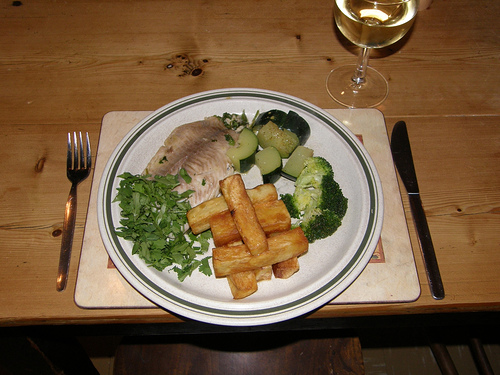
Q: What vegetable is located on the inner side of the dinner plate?
A: Golden brown french fried.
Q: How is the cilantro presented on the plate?
A: Finely chopped.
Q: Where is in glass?
A: Wine.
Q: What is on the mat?
A: Plate of food.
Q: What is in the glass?
A: Wine.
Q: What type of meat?
A: Fish.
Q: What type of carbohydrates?
A: Potatoes.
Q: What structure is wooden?
A: Table.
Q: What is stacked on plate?
A: Potatoes.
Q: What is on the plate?
A: Food.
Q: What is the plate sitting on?
A: A table.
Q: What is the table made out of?
A: Wood.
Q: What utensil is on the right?
A: A knife.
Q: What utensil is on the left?
A: A fork.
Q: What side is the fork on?
A: The left.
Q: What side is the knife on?
A: The right.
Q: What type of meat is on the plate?
A: Fish.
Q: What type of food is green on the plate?
A: Vegetables.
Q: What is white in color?
A: The plate.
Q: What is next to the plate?
A: Knife.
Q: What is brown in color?
A: The fries.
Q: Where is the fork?
A: Next to the plate.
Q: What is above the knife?
A: Glass.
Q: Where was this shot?
A: Table.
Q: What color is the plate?
A: White and green.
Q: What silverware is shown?
A: Fork and knife.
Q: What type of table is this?
A: Wooden.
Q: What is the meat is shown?
A: Fish.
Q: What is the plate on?
A: Placemat.